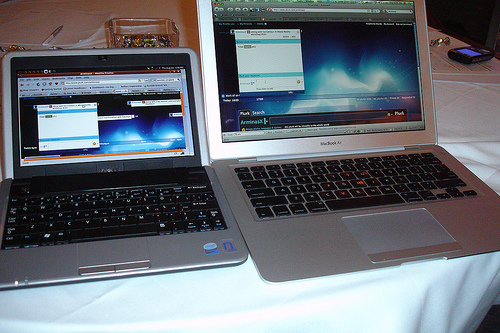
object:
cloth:
[1, 54, 493, 332]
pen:
[25, 49, 80, 50]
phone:
[450, 50, 490, 76]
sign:
[315, 129, 349, 157]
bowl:
[113, 50, 117, 58]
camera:
[74, 100, 80, 106]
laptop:
[1, 115, 229, 173]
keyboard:
[5, 185, 225, 261]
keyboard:
[7, 170, 234, 258]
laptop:
[5, 178, 231, 240]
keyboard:
[1, 110, 241, 292]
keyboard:
[5, 176, 225, 244]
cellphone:
[6, 178, 224, 258]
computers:
[11, 112, 477, 278]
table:
[15, 83, 495, 333]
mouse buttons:
[342, 196, 456, 265]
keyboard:
[226, 142, 478, 236]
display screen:
[215, 7, 427, 147]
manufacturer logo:
[310, 136, 350, 154]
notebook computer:
[4, 47, 251, 299]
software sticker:
[197, 240, 222, 256]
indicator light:
[12, 280, 21, 289]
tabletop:
[6, 2, 498, 331]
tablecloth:
[6, 2, 498, 331]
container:
[102, 0, 187, 50]